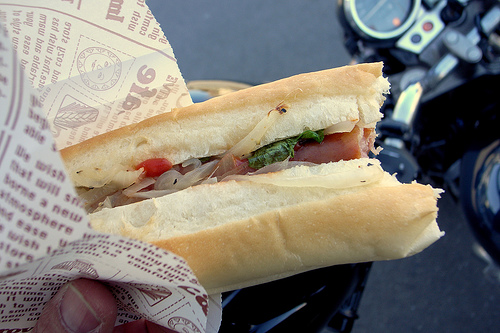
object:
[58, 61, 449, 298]
bread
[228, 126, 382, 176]
meat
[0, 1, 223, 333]
paper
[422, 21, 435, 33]
button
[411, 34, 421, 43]
button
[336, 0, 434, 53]
meter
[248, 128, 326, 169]
lettuce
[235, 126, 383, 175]
ham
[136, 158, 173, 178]
tomato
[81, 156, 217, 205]
onion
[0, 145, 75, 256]
writing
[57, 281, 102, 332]
thumbnail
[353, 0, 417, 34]
gauge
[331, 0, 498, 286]
motorcycle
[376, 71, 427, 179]
handlebar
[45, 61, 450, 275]
sub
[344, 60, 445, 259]
bite taken out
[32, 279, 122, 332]
hand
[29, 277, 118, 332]
man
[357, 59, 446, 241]
eaten area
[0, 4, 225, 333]
wrapping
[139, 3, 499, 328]
cement